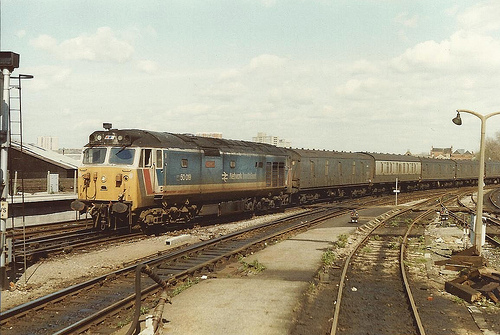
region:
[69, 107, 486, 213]
train on the track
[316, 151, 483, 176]
dirt on the train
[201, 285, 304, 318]
pavement between the tracks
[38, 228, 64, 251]
track train is on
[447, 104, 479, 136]
light on a pole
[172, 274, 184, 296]
grass growing near track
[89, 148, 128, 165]
window on a train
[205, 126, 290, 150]
buildings behind the train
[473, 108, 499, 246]
pole near the track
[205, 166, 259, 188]
name on the train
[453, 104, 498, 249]
A tan-colored light pole.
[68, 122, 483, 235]
A large train on the move.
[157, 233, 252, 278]
A dark rusty train track.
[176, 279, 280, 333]
A paved area on the ground.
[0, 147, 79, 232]
A constructed platform area.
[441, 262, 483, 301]
Pieces of broken wood on the ground.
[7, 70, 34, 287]
A tall medium colored ladder.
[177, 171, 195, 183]
The number on the the train.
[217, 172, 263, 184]
The company logo of the train.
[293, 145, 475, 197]
The train cars behind the front of the train.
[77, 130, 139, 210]
front of the train is yellow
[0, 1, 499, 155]
partly cloudy hazy sky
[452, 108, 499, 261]
metal lamp post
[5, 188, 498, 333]
train tracks in a train yard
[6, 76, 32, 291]
tall metal ladder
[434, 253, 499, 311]
wood scraps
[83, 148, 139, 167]
two train windshields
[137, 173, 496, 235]
wheels on the train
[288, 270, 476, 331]
dark brown muddy spot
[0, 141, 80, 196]
brown building with a white roof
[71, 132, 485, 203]
A train passing by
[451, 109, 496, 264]
street light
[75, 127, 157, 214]
front of the train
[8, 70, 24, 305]
a tall ladder to climb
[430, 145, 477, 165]
houses in the background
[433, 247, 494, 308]
pieces of wood on the ground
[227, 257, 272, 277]
green grass on the ground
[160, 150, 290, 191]
blue train cart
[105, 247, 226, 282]
train tracks the train passes by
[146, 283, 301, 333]
pavement on ground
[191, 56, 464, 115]
clouds in the sky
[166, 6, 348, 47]
the blue part of the sky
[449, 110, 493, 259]
a street light next to the tracks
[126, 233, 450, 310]
train tracks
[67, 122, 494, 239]
a train on the train tracks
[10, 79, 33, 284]
a ladder next to the train tracks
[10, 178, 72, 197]
a fence behind the train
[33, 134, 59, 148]
a building in the distance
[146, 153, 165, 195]
the door of the train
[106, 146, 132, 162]
the windshield on the train